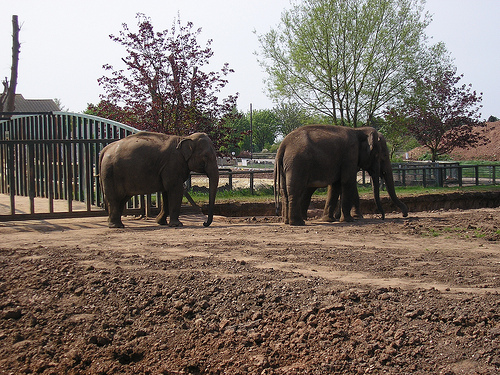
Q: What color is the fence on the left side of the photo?
A: Green.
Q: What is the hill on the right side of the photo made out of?
A: Dirt.